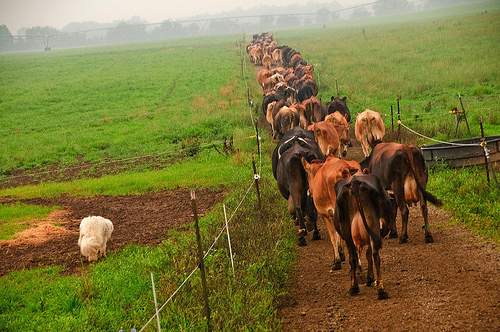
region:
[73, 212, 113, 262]
A furry white dog sniffing grass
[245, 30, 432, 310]
A large herd of cattle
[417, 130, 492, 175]
A large metal tub.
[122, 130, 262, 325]
A metal fence to the left of the cows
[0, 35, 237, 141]
A field of grass to the cows' left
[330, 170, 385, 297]
The first black cow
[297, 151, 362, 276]
The first brown cow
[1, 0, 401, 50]
Fog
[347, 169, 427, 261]
Two pairs of utters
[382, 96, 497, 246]
Fence to the cows' right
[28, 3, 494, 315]
cows walking on a trail through a field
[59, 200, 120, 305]
sheep in a field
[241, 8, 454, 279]
crowded heard of cows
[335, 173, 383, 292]
brown cow with large utters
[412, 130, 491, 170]
water troft in a field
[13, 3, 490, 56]
fog in the distance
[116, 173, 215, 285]
mud in the grass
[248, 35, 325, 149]
line of cows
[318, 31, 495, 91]
field of grass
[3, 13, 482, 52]
trees in the background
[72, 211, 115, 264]
a white furred dog is in a field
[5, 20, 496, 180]
the pasture is green and thick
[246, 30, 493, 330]
the pathway in between the pasture is brown dirt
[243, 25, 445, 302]
a herd of cows are heading out to pasture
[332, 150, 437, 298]
the cattle have full udders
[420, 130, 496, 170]
a water trough is to the right of the cows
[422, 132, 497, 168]
the water trough is round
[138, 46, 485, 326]
the dirt cow path has a fence on both sides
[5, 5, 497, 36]
trees are on the horizon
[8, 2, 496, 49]
it is foggy on the horizon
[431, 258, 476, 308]
part of a pathway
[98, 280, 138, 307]
part of some grass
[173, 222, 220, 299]
part of a stick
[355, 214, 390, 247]
tail of a cow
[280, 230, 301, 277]
edge of the pathway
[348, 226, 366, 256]
udder of a cow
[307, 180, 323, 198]
stomach of a cow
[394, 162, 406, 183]
thigh of a cow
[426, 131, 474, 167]
part of a rope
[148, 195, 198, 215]
part of a ground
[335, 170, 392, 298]
a cow in the road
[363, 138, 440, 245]
a cow in the road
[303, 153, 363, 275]
a cow in the road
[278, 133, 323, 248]
a cow in the road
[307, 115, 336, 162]
a cow in the road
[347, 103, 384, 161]
a cow in the road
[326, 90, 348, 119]
a cow in the road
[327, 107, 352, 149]
a cow in the road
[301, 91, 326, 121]
a cow in the road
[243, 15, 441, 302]
a heard of cows